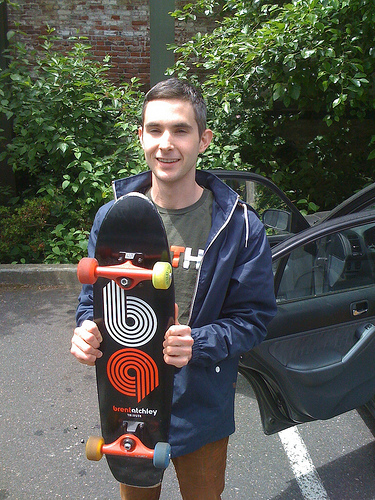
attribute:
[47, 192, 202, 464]
skateboard — red, black, brand name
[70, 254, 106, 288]
wheel — yellow, mounted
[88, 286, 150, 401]
design — red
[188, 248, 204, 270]
letters — white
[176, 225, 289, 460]
jacket — blue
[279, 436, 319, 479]
line — white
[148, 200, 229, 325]
tshirt — red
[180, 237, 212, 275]
h — white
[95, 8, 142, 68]
wall — brick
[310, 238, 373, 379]
door — grey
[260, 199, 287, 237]
mirror — rear view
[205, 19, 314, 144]
shrub — green